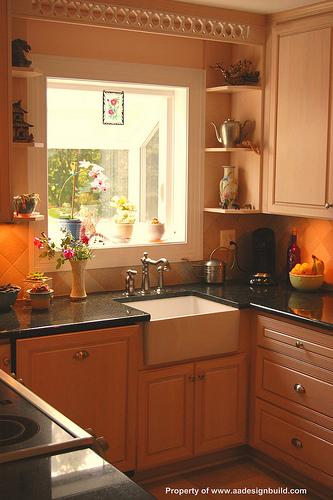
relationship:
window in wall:
[49, 72, 201, 256] [127, 39, 204, 64]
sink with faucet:
[148, 310, 223, 357] [115, 258, 178, 287]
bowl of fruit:
[290, 280, 326, 295] [294, 260, 321, 270]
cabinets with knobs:
[71, 367, 114, 413] [278, 373, 314, 403]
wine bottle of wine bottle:
[287, 228, 302, 285] [289, 239, 304, 271]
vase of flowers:
[210, 160, 244, 209] [52, 231, 99, 258]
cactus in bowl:
[69, 160, 79, 216] [290, 280, 326, 295]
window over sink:
[49, 72, 201, 256] [148, 310, 223, 357]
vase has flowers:
[210, 160, 244, 209] [52, 231, 99, 258]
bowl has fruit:
[290, 280, 326, 295] [294, 260, 321, 270]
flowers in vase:
[52, 231, 99, 258] [210, 160, 244, 209]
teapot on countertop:
[208, 121, 255, 150] [263, 293, 315, 321]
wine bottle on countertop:
[289, 239, 304, 271] [263, 293, 315, 321]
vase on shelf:
[210, 160, 244, 209] [210, 203, 262, 222]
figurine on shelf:
[213, 59, 264, 91] [210, 203, 262, 222]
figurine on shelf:
[14, 35, 39, 73] [210, 203, 262, 222]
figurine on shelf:
[9, 101, 47, 139] [210, 203, 262, 222]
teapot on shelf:
[208, 121, 255, 150] [210, 203, 262, 222]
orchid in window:
[82, 168, 111, 226] [49, 72, 201, 256]